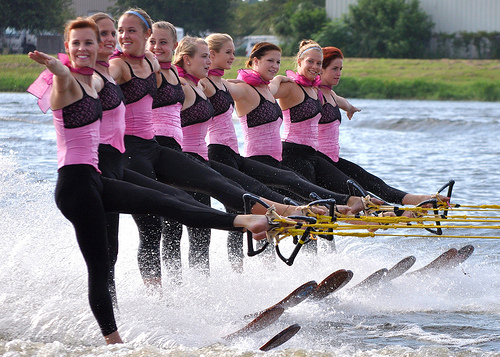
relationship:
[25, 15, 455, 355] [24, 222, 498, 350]
ladies in water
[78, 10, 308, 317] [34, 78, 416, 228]
ladies wears outfit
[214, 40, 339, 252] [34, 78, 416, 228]
lady wears outfit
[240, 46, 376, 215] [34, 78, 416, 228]
lady wears outfit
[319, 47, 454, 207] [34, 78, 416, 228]
lady wears outfit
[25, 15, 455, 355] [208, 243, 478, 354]
ladies on surfboards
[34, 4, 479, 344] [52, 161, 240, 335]
women wearing leggings